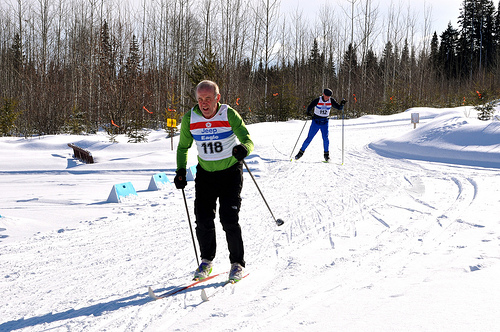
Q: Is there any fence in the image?
A: No, there are no fences.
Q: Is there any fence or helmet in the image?
A: No, there are no fences or helmets.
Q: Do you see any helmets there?
A: No, there are no helmets.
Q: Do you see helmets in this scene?
A: No, there are no helmets.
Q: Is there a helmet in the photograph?
A: No, there are no helmets.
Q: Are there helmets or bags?
A: No, there are no helmets or bags.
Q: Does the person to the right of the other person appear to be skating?
A: Yes, the person is skating.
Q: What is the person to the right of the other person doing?
A: The person is skating.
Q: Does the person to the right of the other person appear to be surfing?
A: No, the person is skating.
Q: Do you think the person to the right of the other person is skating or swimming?
A: The person is skating.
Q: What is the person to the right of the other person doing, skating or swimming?
A: The person is skating.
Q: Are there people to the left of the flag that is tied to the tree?
A: Yes, there is a person to the left of the flag.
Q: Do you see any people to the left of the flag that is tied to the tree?
A: Yes, there is a person to the left of the flag.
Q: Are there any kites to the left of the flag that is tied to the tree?
A: No, there is a person to the left of the flag.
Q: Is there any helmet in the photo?
A: No, there are no helmets.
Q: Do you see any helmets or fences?
A: No, there are no helmets or fences.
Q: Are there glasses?
A: No, there are no glasses.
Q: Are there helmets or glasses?
A: No, there are no glasses or helmets.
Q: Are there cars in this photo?
A: No, there are no cars.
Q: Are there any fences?
A: No, there are no fences.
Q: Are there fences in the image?
A: No, there are no fences.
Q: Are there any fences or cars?
A: No, there are no fences or cars.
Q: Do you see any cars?
A: No, there are no cars.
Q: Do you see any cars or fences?
A: No, there are no cars or fences.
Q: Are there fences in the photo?
A: No, there are no fences.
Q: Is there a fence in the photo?
A: No, there are no fences.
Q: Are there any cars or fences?
A: No, there are no fences or cars.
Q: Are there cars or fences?
A: No, there are no cars or fences.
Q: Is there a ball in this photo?
A: No, there are no balls.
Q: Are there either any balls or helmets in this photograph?
A: No, there are no balls or helmets.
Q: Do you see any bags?
A: No, there are no bags.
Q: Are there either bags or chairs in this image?
A: No, there are no bags or chairs.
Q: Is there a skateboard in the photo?
A: No, there are no skateboards.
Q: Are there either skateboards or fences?
A: No, there are no skateboards or fences.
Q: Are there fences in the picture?
A: No, there are no fences.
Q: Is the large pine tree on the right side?
A: Yes, the pine tree is on the right of the image.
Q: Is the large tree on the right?
A: Yes, the pine tree is on the right of the image.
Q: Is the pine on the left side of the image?
A: No, the pine is on the right of the image.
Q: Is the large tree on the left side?
A: No, the pine is on the right of the image.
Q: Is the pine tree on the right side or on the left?
A: The pine tree is on the right of the image.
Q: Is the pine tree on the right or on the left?
A: The pine tree is on the right of the image.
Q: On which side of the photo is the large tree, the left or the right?
A: The pine tree is on the right of the image.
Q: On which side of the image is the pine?
A: The pine is on the right of the image.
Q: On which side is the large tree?
A: The pine is on the right of the image.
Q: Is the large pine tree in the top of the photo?
A: Yes, the pine is in the top of the image.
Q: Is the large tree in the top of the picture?
A: Yes, the pine is in the top of the image.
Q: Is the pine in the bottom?
A: No, the pine is in the top of the image.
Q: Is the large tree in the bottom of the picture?
A: No, the pine is in the top of the image.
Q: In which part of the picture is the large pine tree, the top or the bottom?
A: The pine tree is in the top of the image.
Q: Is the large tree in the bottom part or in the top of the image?
A: The pine tree is in the top of the image.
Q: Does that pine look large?
A: Yes, the pine is large.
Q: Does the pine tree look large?
A: Yes, the pine tree is large.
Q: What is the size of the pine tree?
A: The pine tree is large.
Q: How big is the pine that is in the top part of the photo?
A: The pine is large.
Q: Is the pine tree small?
A: No, the pine tree is large.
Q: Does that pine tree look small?
A: No, the pine tree is large.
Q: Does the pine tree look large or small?
A: The pine tree is large.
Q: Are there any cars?
A: No, there are no cars.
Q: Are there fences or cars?
A: No, there are no cars or fences.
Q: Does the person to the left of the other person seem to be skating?
A: Yes, the person is skating.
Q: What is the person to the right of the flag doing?
A: The person is skating.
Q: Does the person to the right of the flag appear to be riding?
A: No, the person is skating.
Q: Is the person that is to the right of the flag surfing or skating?
A: The person is skating.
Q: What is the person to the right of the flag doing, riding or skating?
A: The person is skating.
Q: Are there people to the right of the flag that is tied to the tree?
A: No, the person is to the left of the flag.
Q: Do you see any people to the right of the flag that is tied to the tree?
A: No, the person is to the left of the flag.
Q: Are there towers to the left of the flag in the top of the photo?
A: No, there is a person to the left of the flag.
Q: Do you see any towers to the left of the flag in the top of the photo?
A: No, there is a person to the left of the flag.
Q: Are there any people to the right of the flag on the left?
A: Yes, there is a person to the right of the flag.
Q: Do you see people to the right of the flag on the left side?
A: Yes, there is a person to the right of the flag.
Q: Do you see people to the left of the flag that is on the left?
A: No, the person is to the right of the flag.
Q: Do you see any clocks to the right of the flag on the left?
A: No, there is a person to the right of the flag.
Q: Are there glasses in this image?
A: No, there are no glasses.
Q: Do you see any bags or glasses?
A: No, there are no glasses or bags.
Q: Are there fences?
A: No, there are no fences.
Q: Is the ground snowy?
A: Yes, the ground is snowy.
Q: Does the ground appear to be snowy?
A: Yes, the ground is snowy.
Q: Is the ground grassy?
A: No, the ground is snowy.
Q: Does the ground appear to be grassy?
A: No, the ground is snowy.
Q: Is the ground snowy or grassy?
A: The ground is snowy.